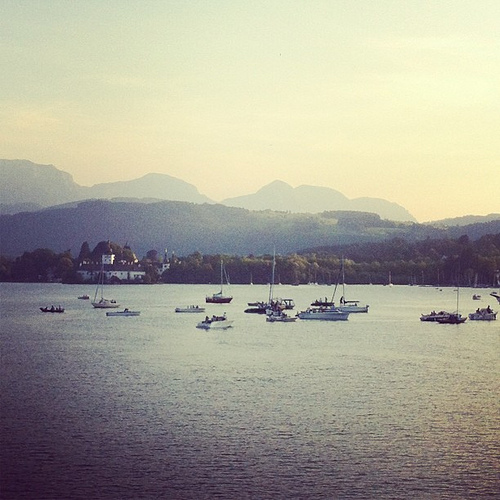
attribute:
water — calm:
[6, 280, 493, 498]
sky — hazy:
[4, 5, 498, 194]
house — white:
[95, 242, 149, 283]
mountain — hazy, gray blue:
[84, 167, 216, 207]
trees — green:
[282, 249, 354, 276]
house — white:
[70, 236, 155, 285]